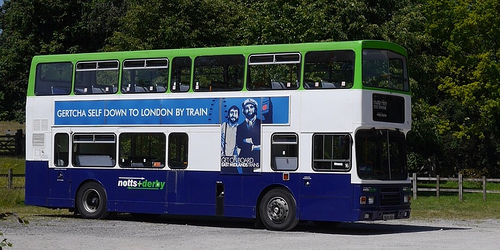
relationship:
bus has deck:
[23, 38, 416, 231] [25, 37, 406, 63]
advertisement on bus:
[39, 91, 259, 169] [23, 38, 416, 231]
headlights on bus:
[334, 171, 437, 226] [23, 38, 416, 231]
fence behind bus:
[0, 163, 498, 200] [23, 38, 416, 231]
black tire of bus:
[258, 188, 300, 230] [13, 19, 332, 246]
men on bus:
[222, 98, 259, 169] [23, 38, 416, 231]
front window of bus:
[358, 126, 410, 183] [23, 38, 416, 231]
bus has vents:
[23, 38, 416, 231] [29, 119, 51, 151]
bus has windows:
[23, 38, 416, 231] [51, 130, 191, 170]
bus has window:
[23, 38, 416, 231] [370, 100, 405, 121]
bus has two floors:
[23, 38, 416, 231] [41, 60, 348, 187]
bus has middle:
[23, 38, 416, 231] [22, 96, 411, 170]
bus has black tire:
[23, 38, 416, 231] [73, 179, 113, 219]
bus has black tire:
[23, 38, 416, 231] [257, 185, 299, 227]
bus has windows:
[23, 38, 416, 231] [24, 36, 413, 178]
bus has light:
[23, 38, 416, 231] [362, 195, 376, 207]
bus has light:
[23, 38, 416, 231] [402, 198, 412, 208]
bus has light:
[23, 38, 416, 231] [359, 180, 374, 195]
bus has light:
[23, 38, 416, 231] [403, 182, 413, 194]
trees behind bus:
[419, 49, 494, 149] [23, 38, 416, 231]